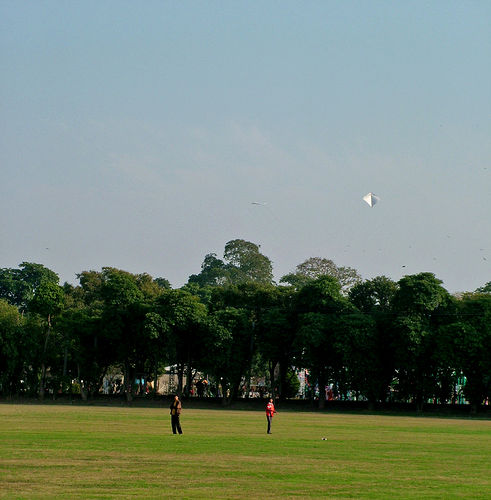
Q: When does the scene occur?
A: Daytime.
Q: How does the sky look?
A: Blue.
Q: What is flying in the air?
A: Kites.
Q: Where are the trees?
A: Behind the people.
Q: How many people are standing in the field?
A: Two.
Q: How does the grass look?
A: Green with some brown patches.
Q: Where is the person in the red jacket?
A: On the right.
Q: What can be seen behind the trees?
A: Buildings.